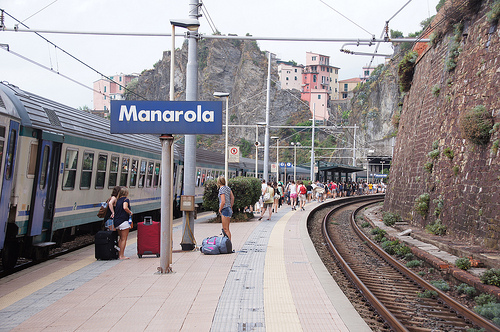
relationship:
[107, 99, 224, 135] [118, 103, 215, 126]
sign with letters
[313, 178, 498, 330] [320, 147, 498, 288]
train tracks going around curve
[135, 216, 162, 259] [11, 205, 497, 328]
suitcase sitting on ground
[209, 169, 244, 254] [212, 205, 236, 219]
woman wearing shorts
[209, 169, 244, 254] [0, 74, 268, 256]
woman waiting to board train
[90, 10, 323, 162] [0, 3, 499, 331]
rock blocking scene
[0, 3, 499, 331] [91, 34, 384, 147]
scene of city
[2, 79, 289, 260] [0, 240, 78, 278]
train waiting on tracks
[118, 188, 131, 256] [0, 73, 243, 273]
woman waiting to get on train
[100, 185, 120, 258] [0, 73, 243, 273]
woman waiting to get on train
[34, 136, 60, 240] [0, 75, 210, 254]
door to train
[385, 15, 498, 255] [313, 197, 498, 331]
wall next to train tracks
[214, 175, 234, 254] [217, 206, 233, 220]
woman wearing shorts